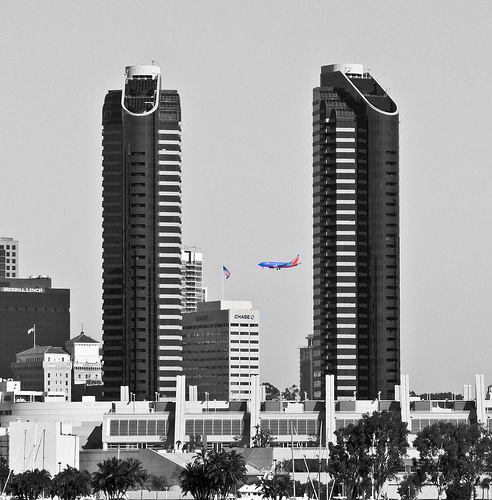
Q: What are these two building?
A: Towers.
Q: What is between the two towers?
A: An airplane.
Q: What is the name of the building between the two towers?
A: Chase building.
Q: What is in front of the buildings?
A: Trees.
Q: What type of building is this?
A: Multi story.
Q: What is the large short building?
A: A stadium.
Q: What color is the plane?
A: Blue.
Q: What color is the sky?
A: Gray.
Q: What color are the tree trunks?
A: Gray.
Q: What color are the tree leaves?
A: Gray.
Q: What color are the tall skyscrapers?
A: Gray.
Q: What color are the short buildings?
A: White.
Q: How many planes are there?
A: One.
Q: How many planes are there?
A: One.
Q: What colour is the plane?
A: Red and blue.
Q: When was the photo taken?
A: Daytime.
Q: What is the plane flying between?
A: Two buildings.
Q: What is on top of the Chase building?
A: A flag.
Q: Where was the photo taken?
A: Near the airport.